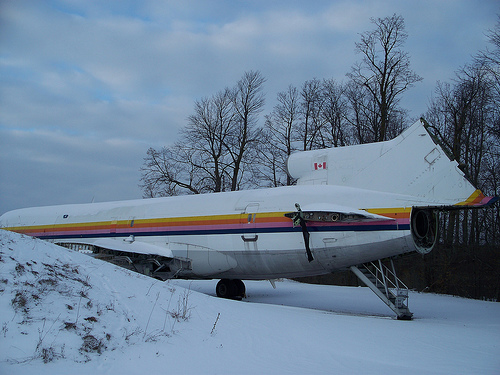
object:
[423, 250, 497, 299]
bush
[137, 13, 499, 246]
trees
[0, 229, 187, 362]
hill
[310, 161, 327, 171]
canadian flag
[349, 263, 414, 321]
ladder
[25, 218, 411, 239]
stripes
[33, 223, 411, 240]
stripe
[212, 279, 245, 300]
wheel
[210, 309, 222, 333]
stick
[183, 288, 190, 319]
stick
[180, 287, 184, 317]
stick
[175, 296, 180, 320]
stick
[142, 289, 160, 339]
stick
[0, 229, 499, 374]
snow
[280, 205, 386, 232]
broken wing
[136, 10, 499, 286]
forest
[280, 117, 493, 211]
tail sections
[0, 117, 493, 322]
plane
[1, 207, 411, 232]
stripes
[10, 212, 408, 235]
stripes